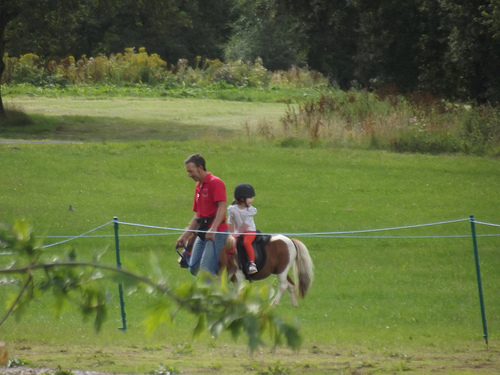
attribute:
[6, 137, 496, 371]
grass — green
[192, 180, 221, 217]
shirt — red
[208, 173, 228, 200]
sleeves — short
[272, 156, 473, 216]
grass — lush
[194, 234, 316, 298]
pony — white, brown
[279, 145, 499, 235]
lawn — mown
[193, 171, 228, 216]
shirt — red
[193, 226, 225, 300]
jeans — blue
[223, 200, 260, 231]
shirt — white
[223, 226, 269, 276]
leggings — orange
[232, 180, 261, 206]
helmet — black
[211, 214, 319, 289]
pony — brown, white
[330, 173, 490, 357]
grass — green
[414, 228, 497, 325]
pole — green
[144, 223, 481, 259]
rope — grey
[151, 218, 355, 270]
pony — brown, white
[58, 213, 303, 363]
branch — green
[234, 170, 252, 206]
helmet — black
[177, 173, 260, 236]
shirt — red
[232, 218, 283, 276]
saddle — black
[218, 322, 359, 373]
leaf — green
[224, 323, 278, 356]
leaf — green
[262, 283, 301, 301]
leaf — green